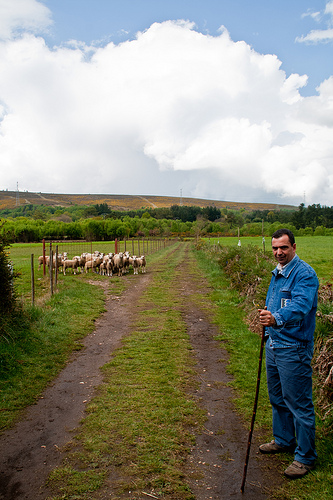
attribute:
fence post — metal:
[28, 252, 37, 307]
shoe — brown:
[257, 439, 278, 452]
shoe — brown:
[284, 459, 309, 477]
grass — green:
[41, 243, 199, 499]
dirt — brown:
[0, 240, 282, 498]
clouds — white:
[1, 2, 332, 205]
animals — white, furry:
[38, 250, 148, 276]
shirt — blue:
[260, 254, 320, 349]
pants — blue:
[264, 348, 315, 461]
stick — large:
[239, 304, 268, 491]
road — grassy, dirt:
[0, 240, 332, 498]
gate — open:
[40, 238, 118, 273]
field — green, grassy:
[0, 240, 167, 298]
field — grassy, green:
[202, 235, 332, 282]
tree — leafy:
[13, 220, 46, 241]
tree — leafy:
[81, 218, 105, 239]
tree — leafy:
[141, 214, 162, 237]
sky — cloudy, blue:
[45, 5, 311, 194]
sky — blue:
[250, 6, 292, 45]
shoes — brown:
[251, 432, 323, 488]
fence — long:
[19, 209, 187, 294]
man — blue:
[252, 223, 311, 290]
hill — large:
[17, 185, 253, 217]